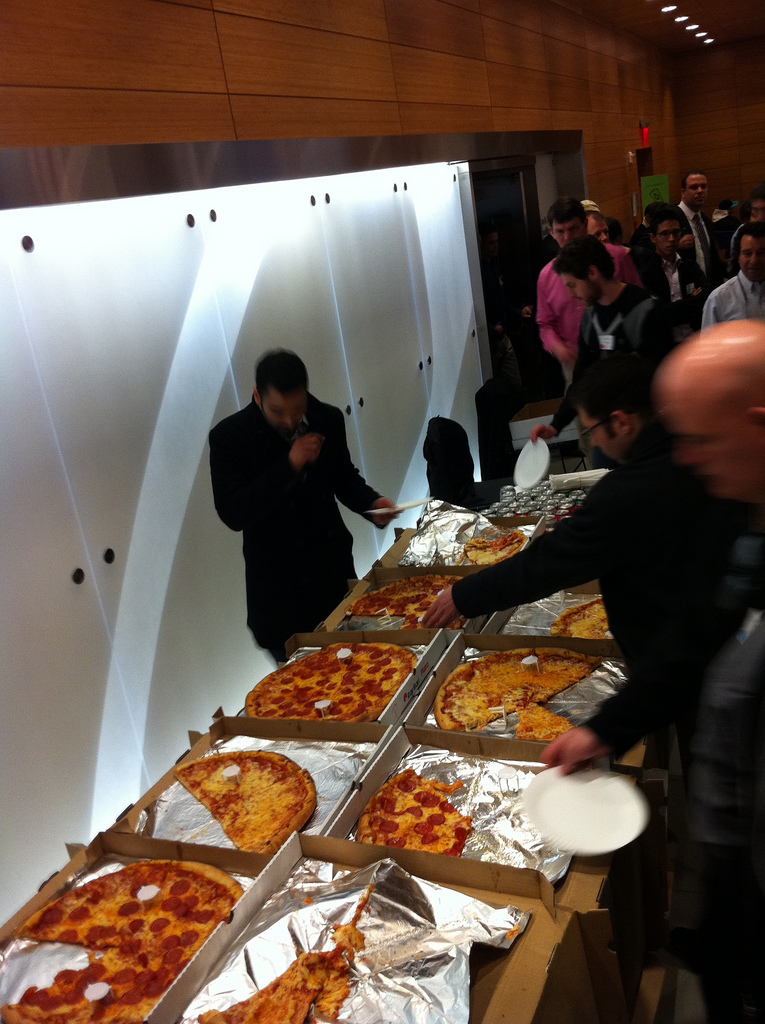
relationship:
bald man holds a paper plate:
[536, 317, 740, 967] [523, 759, 648, 857]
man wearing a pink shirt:
[532, 194, 644, 367] [532, 248, 595, 352]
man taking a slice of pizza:
[429, 354, 741, 648] [366, 571, 449, 626]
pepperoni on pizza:
[415, 801, 458, 856] [351, 770, 480, 861]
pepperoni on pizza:
[408, 790, 439, 817] [345, 765, 474, 854]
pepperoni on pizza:
[415, 788, 438, 804] [374, 781, 464, 851]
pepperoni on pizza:
[363, 677, 385, 695] [296, 642, 383, 719]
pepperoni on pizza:
[167, 898, 212, 927] [107, 866, 207, 941]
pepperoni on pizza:
[312, 657, 339, 684] [277, 649, 371, 703]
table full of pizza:
[61, 637, 577, 983] [278, 655, 397, 724]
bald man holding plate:
[540, 317, 765, 1023] [536, 773, 629, 855]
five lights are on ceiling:
[660, 6, 714, 44] [711, 12, 741, 42]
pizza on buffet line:
[354, 768, 472, 854] [4, 469, 645, 1022]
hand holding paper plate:
[541, 720, 610, 775] [523, 765, 650, 857]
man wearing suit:
[207, 344, 400, 666] [206, 395, 388, 659]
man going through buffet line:
[207, 344, 400, 666] [4, 469, 645, 1022]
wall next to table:
[0, 152, 492, 930] [0, 469, 651, 1023]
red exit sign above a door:
[635, 96, 664, 151] [517, 198, 583, 214]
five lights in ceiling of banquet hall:
[654, 78, 726, 94] [36, 616, 732, 1024]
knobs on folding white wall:
[42, 508, 140, 608] [40, 678, 91, 761]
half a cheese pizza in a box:
[160, 719, 335, 845] [172, 836, 234, 856]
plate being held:
[534, 771, 632, 860] [584, 710, 606, 739]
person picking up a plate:
[558, 233, 645, 370] [510, 409, 569, 525]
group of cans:
[484, 437, 579, 542] [495, 469, 575, 549]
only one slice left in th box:
[218, 939, 359, 1024] [271, 925, 497, 1024]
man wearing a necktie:
[672, 167, 726, 258] [702, 213, 733, 292]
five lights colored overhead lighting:
[660, 6, 714, 44] [538, 157, 710, 166]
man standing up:
[207, 348, 400, 669] [193, 600, 219, 651]